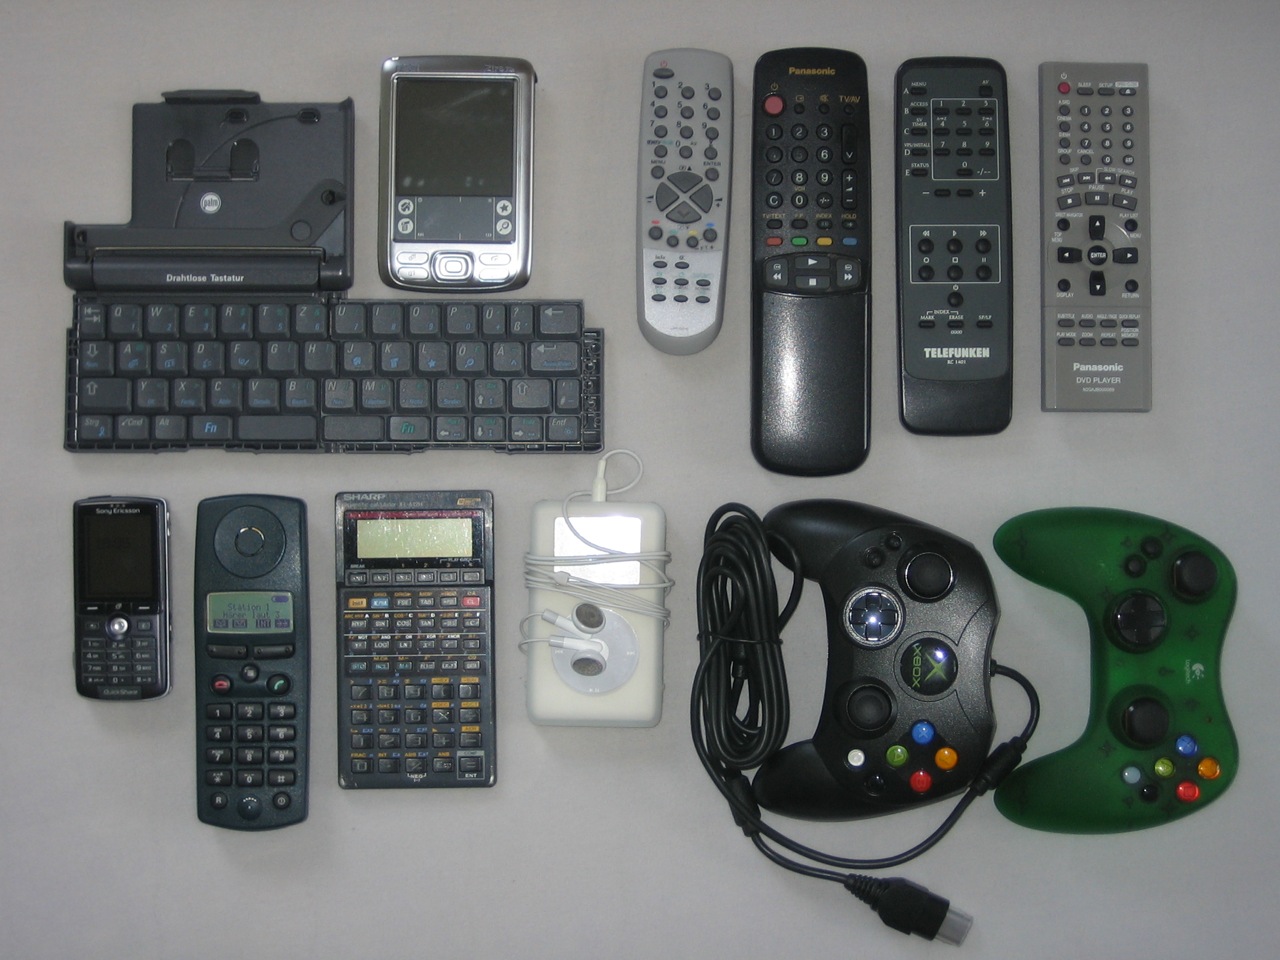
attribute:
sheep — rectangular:
[186, 487, 319, 841]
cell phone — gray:
[52, 487, 181, 706]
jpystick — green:
[976, 487, 1255, 843]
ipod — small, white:
[511, 444, 682, 742]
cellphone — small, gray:
[365, 39, 557, 304]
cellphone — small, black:
[62, 487, 186, 715]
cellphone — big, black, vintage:
[188, 487, 325, 838]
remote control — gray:
[1020, 49, 1175, 431]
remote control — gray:
[625, 34, 745, 375]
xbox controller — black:
[685, 486, 1045, 948]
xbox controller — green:
[978, 497, 1261, 853]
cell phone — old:
[68, 494, 172, 701]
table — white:
[7, 12, 1275, 952]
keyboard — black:
[70, 287, 584, 454]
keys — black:
[1050, 210, 1150, 300]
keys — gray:
[645, 66, 724, 310]